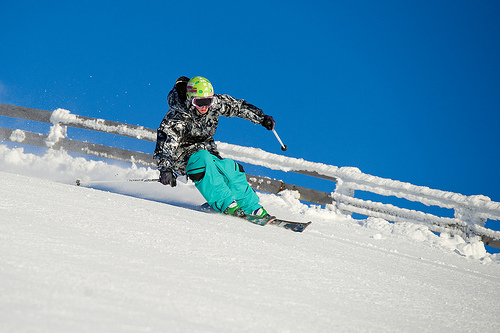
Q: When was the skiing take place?
A: Daytime.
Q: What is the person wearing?
A: Winter clothes.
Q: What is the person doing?
A: Skiing.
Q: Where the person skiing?
A: On the slope.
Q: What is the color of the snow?
A: White.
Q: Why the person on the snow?
A: Skiing.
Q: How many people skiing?
A: One.